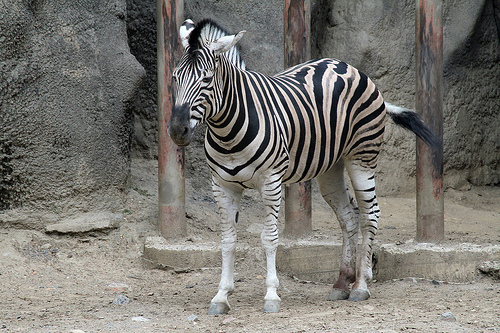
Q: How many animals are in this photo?
A: One.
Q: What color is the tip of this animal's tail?
A: Black.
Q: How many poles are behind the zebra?
A: Three.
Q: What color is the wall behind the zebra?
A: Gray.